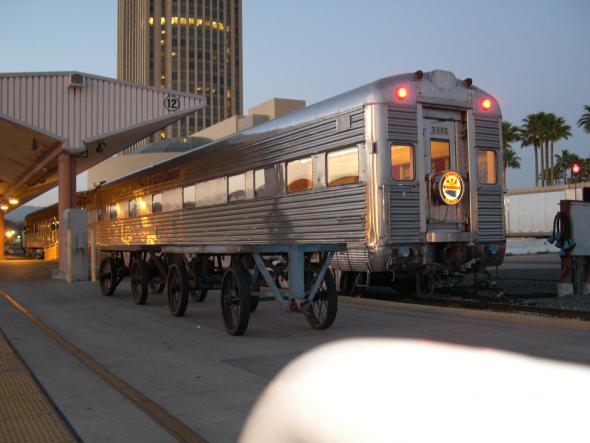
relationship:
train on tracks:
[21, 67, 511, 293] [89, 237, 579, 317]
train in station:
[23, 70, 511, 294] [6, 68, 383, 440]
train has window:
[85, 64, 507, 292] [220, 165, 252, 203]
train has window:
[23, 70, 511, 294] [177, 184, 202, 211]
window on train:
[123, 191, 140, 223] [85, 64, 507, 292]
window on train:
[93, 144, 359, 216] [25, 67, 506, 337]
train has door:
[85, 64, 507, 292] [420, 101, 470, 226]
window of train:
[285, 154, 315, 189] [85, 64, 507, 292]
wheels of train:
[339, 261, 496, 294] [21, 67, 511, 293]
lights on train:
[396, 82, 494, 110] [21, 67, 511, 293]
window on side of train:
[322, 144, 360, 189] [21, 67, 511, 293]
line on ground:
[2, 284, 202, 440] [4, 255, 588, 437]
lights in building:
[152, 15, 229, 30] [117, 3, 241, 146]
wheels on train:
[213, 242, 354, 335] [85, 64, 507, 292]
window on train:
[422, 125, 462, 176] [85, 64, 507, 292]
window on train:
[322, 132, 372, 189] [85, 64, 507, 292]